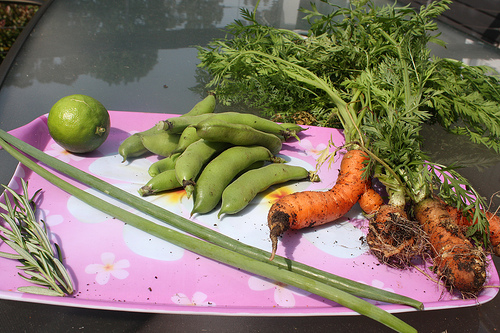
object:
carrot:
[265, 148, 364, 262]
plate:
[0, 110, 499, 317]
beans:
[215, 162, 310, 219]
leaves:
[397, 161, 493, 247]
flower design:
[67, 151, 369, 263]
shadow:
[0, 0, 225, 89]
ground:
[0, 0, 498, 193]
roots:
[267, 227, 282, 262]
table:
[0, 69, 499, 332]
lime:
[46, 94, 110, 154]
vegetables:
[414, 197, 488, 299]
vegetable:
[0, 130, 424, 311]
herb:
[0, 177, 74, 298]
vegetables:
[445, 202, 497, 257]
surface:
[0, 124, 484, 307]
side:
[0, 109, 44, 218]